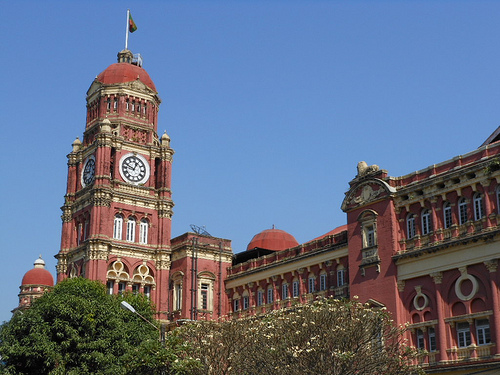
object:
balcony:
[446, 343, 500, 362]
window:
[405, 212, 416, 240]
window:
[419, 208, 432, 236]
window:
[442, 200, 455, 231]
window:
[457, 197, 469, 225]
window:
[473, 191, 489, 222]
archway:
[411, 312, 421, 324]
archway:
[423, 310, 433, 320]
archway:
[452, 301, 467, 317]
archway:
[470, 296, 488, 313]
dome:
[246, 224, 299, 251]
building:
[17, 0, 499, 374]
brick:
[381, 225, 392, 235]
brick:
[380, 284, 397, 304]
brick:
[364, 285, 374, 293]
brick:
[350, 274, 361, 281]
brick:
[348, 241, 360, 249]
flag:
[123, 7, 138, 50]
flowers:
[160, 295, 435, 375]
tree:
[0, 275, 208, 375]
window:
[417, 326, 438, 357]